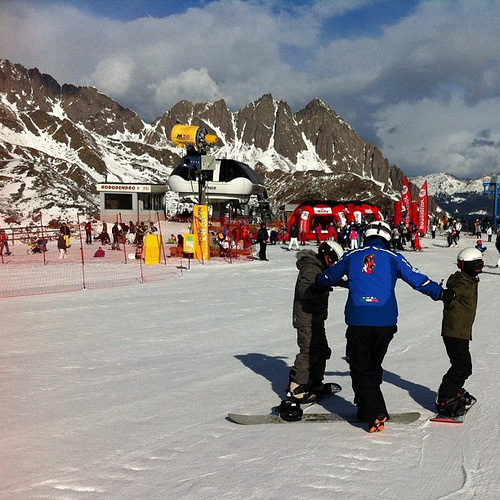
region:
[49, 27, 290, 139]
the sky is cloudy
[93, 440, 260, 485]
tracks are in the snow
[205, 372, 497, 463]
the man is on a snowboard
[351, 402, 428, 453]
the man is weraing tennis shoes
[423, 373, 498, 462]
the man is on a snowboard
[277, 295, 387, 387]
the man is in a snowsuit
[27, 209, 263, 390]
the net is red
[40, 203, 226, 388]
people are behind the net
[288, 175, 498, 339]
the tent is red and white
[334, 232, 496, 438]
the coat is blue and white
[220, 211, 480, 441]
people standing on skis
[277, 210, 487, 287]
the people are wearing helmets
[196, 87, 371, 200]
rocks with snow on them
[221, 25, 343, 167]
the rocks are huge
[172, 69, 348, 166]
the rocks are jagged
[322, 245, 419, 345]
the jacket is blue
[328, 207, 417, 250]
the helmet is white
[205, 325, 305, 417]
shadow is on the snow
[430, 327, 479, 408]
the pants are black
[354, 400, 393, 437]
the bottom of the shoe is orange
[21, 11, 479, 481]
winter season at a resort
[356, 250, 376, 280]
logo on the back of a man's jacket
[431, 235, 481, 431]
boy on a snowboard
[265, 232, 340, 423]
boy on snow skis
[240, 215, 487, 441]
young men on boards and a man without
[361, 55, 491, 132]
gray cloudy sky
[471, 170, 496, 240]
blue pylon for ski lift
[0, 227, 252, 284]
red fencing at the edge of the ski lift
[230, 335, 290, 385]
shadow of a skier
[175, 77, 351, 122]
jagged snowy mountain tops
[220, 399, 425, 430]
long grey snow board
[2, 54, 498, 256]
rocky grey mountains covered in snow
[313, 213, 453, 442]
person in a blue ski jacket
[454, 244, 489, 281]
kid's white plastic helmet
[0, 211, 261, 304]
orange plastic mesh snow fence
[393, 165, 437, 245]
tall red flags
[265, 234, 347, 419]
person on a black snow board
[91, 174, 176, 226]
small white building with many windows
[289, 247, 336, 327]
fur lined black winter coat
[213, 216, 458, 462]
a person with one foot on a snowboard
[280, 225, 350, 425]
a kid holding on to a person while snowboarding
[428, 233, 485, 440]
a kid holding on to a person while snowboarding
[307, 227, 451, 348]
a blue jacket on a person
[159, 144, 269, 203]
a white skii lift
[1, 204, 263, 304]
a red boundery net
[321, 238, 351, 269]
a white snowboard helmet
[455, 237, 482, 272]
a white snowboard helmet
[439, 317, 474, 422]
black snowboarding pants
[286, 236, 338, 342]
a grey jacket